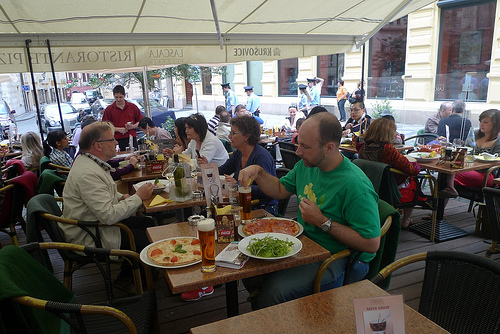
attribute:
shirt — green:
[277, 154, 379, 261]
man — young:
[102, 81, 137, 148]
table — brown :
[147, 198, 333, 295]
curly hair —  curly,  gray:
[229, 117, 262, 145]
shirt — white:
[58, 150, 142, 260]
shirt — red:
[88, 105, 145, 133]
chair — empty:
[364, 246, 499, 332]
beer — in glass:
[196, 219, 216, 271]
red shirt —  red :
[376, 147, 413, 167]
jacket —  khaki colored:
[57, 156, 140, 250]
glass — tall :
[198, 217, 217, 271]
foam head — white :
[196, 217, 213, 229]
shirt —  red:
[105, 106, 143, 138]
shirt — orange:
[333, 85, 349, 102]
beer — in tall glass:
[197, 217, 218, 274]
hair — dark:
[44, 128, 65, 157]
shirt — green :
[271, 146, 386, 266]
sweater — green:
[1, 242, 77, 332]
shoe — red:
[177, 277, 222, 305]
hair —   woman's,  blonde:
[371, 121, 394, 142]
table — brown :
[136, 202, 336, 315]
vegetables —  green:
[246, 235, 293, 255]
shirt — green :
[276, 148, 383, 280]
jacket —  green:
[0, 238, 76, 330]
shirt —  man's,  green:
[282, 155, 388, 263]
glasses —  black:
[98, 135, 115, 145]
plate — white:
[235, 213, 305, 236]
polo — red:
[100, 95, 145, 140]